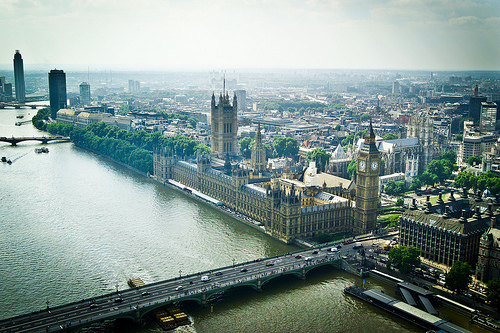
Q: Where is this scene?
A: London.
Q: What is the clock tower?
A: Big ben.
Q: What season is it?
A: Summer.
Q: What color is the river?
A: Brown.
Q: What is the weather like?
A: Sunny.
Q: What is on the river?
A: Boats.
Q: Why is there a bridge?
A: Cross the river.